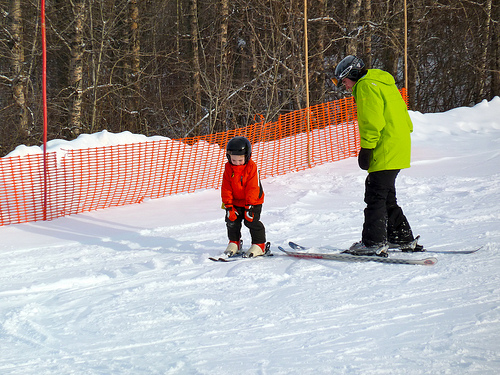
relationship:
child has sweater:
[220, 134, 271, 265] [228, 163, 260, 205]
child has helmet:
[220, 134, 271, 265] [217, 134, 253, 155]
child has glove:
[220, 134, 271, 265] [231, 205, 262, 221]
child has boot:
[220, 134, 271, 265] [248, 236, 271, 250]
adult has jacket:
[334, 41, 418, 273] [357, 76, 410, 169]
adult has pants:
[334, 41, 418, 273] [364, 174, 418, 248]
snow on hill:
[92, 272, 143, 308] [331, 283, 385, 314]